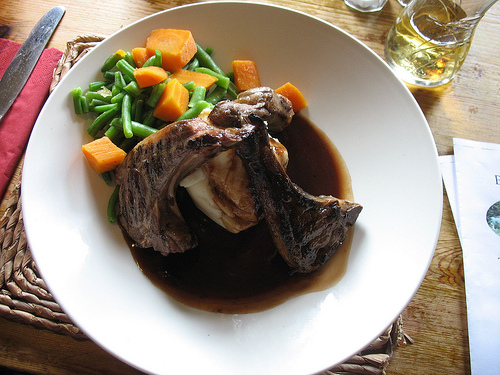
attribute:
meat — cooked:
[109, 83, 356, 273]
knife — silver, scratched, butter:
[6, 1, 71, 103]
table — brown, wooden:
[2, 3, 499, 364]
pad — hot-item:
[3, 244, 28, 298]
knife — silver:
[0, 4, 65, 126]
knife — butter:
[6, 1, 73, 76]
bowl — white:
[26, 14, 446, 354]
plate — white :
[15, 0, 447, 373]